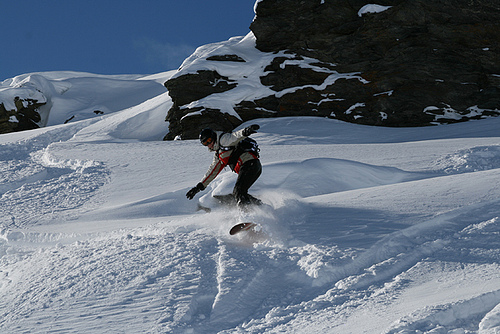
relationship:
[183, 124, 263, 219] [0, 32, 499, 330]
man on slope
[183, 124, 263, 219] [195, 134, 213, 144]
man wearing snow goggles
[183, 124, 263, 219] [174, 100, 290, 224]
man wearing goggles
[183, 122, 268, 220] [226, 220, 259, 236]
man on snowboard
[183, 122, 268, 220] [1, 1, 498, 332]
man on mountain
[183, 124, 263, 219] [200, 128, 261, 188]
man wearing jacket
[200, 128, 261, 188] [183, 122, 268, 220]
jacket on man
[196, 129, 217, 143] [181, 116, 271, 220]
helmet on man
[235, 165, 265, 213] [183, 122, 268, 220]
pants on man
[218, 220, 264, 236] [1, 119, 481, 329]
snowboard in snow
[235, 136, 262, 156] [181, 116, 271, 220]
backpack on man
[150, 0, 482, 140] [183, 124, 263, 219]
cliff behind man